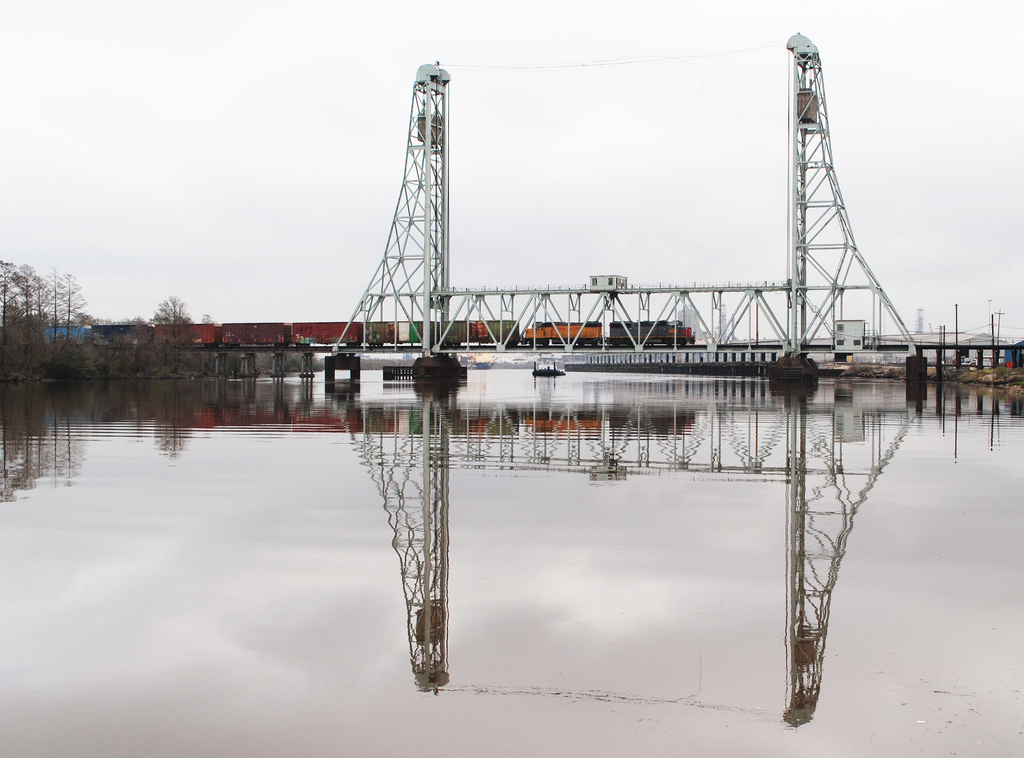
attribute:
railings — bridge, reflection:
[320, 27, 928, 364]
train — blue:
[4, 312, 700, 355]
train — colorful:
[9, 315, 705, 363]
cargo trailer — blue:
[48, 310, 144, 360]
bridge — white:
[135, 35, 928, 381]